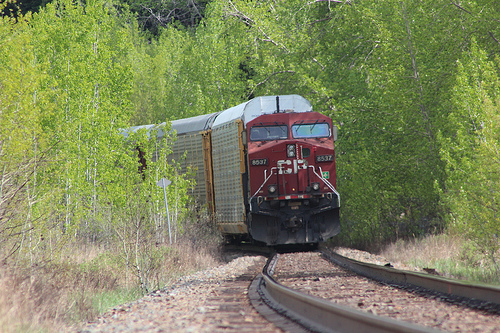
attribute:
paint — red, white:
[244, 108, 339, 201]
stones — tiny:
[115, 278, 191, 312]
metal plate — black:
[246, 190, 348, 247]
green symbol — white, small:
[319, 169, 329, 180]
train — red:
[94, 88, 359, 268]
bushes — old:
[2, 137, 162, 296]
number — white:
[250, 158, 267, 165]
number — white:
[315, 153, 332, 163]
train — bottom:
[115, 87, 350, 258]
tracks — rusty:
[260, 239, 496, 331]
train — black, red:
[109, 93, 339, 247]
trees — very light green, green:
[1, 5, 498, 252]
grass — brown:
[6, 234, 209, 327]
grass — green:
[412, 250, 497, 284]